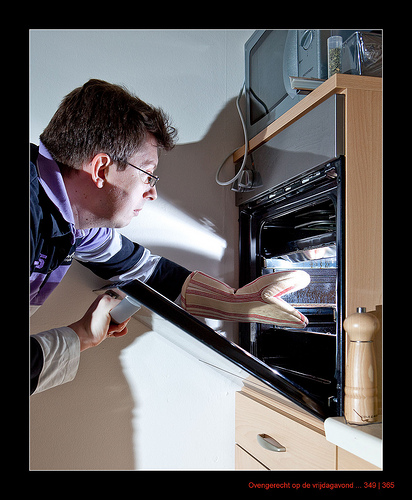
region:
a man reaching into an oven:
[27, 78, 310, 394]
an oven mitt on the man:
[182, 268, 310, 330]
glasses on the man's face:
[110, 152, 158, 187]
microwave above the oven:
[243, 30, 340, 137]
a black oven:
[90, 93, 346, 419]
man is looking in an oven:
[32, 78, 310, 393]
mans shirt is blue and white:
[27, 143, 192, 396]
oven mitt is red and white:
[179, 267, 310, 332]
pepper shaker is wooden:
[343, 307, 380, 426]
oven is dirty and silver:
[261, 169, 336, 385]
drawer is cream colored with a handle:
[235, 390, 336, 470]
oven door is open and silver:
[90, 282, 331, 425]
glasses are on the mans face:
[115, 156, 157, 186]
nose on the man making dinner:
[143, 183, 157, 201]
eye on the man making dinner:
[140, 167, 151, 179]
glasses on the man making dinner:
[120, 157, 163, 187]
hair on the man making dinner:
[37, 76, 175, 165]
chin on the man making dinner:
[111, 216, 132, 226]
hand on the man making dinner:
[74, 285, 132, 348]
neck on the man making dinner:
[29, 140, 91, 226]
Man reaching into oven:
[1, 77, 351, 414]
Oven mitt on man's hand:
[178, 268, 310, 324]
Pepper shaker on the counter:
[342, 305, 378, 426]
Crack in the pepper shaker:
[350, 408, 374, 422]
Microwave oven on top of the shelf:
[234, 22, 332, 137]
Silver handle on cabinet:
[255, 431, 288, 453]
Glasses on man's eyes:
[105, 153, 163, 189]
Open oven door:
[91, 274, 327, 427]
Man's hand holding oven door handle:
[70, 286, 140, 351]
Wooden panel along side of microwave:
[345, 74, 399, 425]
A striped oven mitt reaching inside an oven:
[180, 264, 319, 329]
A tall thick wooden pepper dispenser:
[336, 304, 382, 431]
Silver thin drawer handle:
[251, 428, 289, 456]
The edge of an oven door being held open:
[102, 276, 315, 427]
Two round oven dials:
[229, 163, 255, 194]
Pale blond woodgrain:
[351, 187, 376, 287]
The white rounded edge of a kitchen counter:
[321, 412, 376, 459]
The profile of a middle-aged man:
[53, 85, 174, 233]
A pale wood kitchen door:
[229, 393, 335, 468]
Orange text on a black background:
[243, 478, 400, 498]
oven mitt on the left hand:
[176, 260, 313, 331]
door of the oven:
[92, 272, 320, 425]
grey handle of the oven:
[99, 293, 144, 323]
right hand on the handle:
[68, 291, 139, 353]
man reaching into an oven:
[28, 74, 308, 397]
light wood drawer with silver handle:
[232, 386, 337, 470]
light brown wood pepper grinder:
[339, 305, 380, 425]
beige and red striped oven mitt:
[178, 265, 311, 329]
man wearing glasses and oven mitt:
[29, 77, 311, 393]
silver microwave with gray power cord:
[212, 28, 382, 188]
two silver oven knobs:
[227, 165, 253, 193]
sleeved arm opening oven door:
[29, 290, 141, 396]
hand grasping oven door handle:
[84, 292, 139, 348]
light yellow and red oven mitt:
[182, 256, 315, 333]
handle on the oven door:
[94, 298, 141, 325]